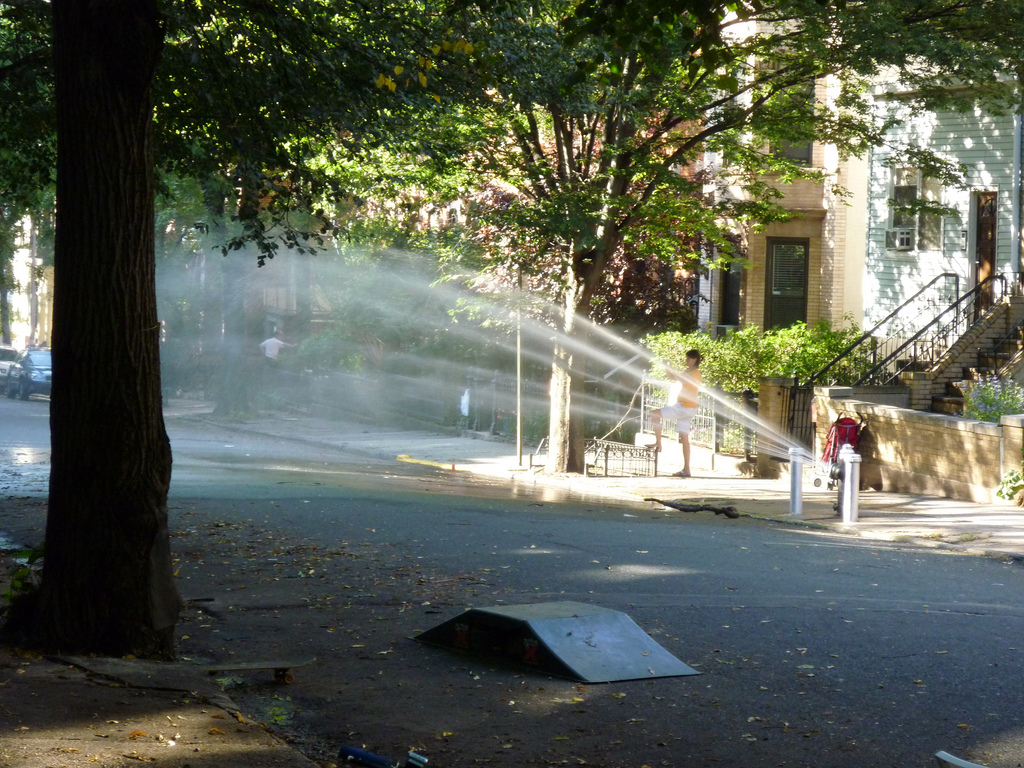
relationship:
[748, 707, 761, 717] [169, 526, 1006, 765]
leaf on ground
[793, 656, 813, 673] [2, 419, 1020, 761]
leaf on ground.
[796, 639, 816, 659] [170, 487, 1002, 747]
leaf on ground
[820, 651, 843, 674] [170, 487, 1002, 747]
leaf on ground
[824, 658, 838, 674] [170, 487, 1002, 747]
leaf on ground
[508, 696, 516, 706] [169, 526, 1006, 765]
leaf on ground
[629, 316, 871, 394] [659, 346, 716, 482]
shrubbery behind person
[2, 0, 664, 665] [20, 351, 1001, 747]
tree casting shade on street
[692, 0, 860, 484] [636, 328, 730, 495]
building behind person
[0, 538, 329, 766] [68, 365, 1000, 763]
sidewalk next to road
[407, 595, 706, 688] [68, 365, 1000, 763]
ramp on road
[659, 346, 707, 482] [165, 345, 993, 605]
person on sidewalk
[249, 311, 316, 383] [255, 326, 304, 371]
shirt on man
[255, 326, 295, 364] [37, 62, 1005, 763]
man standing outside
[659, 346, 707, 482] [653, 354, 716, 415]
person wearing shirt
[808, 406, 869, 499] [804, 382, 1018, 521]
carriage next to wall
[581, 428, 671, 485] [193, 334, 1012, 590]
bench on the sidewalk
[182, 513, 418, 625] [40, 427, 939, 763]
leafs on the ground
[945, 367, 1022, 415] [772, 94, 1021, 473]
flowers in front of house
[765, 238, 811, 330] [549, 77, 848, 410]
window on building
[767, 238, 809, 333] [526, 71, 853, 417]
window on building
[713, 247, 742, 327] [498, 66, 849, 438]
window on building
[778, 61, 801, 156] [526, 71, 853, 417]
window on building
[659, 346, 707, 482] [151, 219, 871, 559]
person behind water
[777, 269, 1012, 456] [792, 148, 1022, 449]
stairs into building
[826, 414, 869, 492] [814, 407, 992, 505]
carriage parked on side of wall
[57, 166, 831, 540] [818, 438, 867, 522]
water spraying out of hydrant